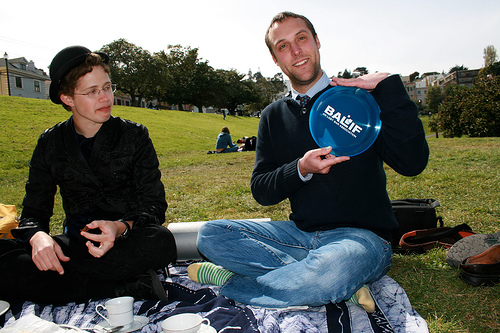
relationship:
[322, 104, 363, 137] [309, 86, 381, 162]
writing on frisbee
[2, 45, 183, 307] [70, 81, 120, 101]
people wearing glasses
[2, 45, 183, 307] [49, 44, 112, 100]
people wearing hat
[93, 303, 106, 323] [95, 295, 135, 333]
handle on mug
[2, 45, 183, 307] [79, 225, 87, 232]
people holding object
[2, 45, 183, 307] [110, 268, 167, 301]
people wearing shoes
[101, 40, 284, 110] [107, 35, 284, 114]
leaves are on trees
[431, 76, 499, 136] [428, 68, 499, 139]
leaves are on trees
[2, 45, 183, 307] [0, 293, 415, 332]
people having picnic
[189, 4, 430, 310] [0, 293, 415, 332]
person having picnic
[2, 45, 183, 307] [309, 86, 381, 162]
people looking at frisbee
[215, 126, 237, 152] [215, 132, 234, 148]
woman wearing hoodie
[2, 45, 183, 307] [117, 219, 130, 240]
people wearing watch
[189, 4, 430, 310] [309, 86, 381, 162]
person holding frisbee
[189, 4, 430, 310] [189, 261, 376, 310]
person wearing socks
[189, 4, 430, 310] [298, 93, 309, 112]
person wearing tie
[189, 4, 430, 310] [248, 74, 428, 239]
person wearing sweater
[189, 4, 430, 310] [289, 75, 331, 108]
person wearing dress shirt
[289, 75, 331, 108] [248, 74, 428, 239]
dress shirt under sweater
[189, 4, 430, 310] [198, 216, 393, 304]
person wearing jeans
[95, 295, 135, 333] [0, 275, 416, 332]
tea cup on blanket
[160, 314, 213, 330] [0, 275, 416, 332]
tea cup on blanket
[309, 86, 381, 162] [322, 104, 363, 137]
frisbee has writing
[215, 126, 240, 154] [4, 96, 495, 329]
woman on grass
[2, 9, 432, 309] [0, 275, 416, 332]
people on blanket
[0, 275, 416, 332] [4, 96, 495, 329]
blanket on grass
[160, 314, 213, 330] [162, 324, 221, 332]
tea cup on saucer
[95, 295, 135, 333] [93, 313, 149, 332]
mug on saucer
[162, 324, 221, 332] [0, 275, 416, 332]
saucer on blanket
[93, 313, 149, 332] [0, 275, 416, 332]
saucer on blanket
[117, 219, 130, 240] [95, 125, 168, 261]
watch on arm